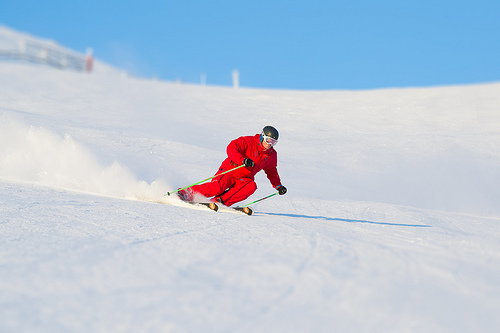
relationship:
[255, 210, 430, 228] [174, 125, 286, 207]
shadow of he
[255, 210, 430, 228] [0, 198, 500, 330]
shadow on snow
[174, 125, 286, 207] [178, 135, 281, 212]
he wearing clothes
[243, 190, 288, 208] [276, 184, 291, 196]
snow pole on left hand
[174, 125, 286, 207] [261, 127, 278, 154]
he wearing goggles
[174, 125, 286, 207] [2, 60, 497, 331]
he on ski slope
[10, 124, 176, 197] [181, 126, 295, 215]
snow behind skier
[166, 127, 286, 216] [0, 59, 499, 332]
he skiing on hill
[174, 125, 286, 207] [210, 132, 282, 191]
he wearing clothes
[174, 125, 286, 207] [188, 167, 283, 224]
he wearing pants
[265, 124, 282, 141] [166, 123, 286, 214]
helmet of him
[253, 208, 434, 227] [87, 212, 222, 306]
shadow cast on snow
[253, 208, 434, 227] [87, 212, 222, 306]
shadow on snow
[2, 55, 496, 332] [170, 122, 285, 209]
snow behind skier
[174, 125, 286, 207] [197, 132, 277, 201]
he wearing jumpsuit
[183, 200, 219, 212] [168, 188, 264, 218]
ski digging through snow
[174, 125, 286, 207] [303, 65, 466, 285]
he skiing down slope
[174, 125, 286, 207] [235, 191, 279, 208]
he holds snow pole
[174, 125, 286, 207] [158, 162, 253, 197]
he holds pole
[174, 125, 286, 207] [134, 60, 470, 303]
he going down hill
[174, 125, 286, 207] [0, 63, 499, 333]
he skiing down ski slope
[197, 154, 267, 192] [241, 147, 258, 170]
pole in hand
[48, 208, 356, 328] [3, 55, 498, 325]
ski marks on hill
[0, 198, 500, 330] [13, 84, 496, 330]
snow above ground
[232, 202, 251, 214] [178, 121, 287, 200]
ski of skier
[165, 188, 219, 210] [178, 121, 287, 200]
ski of skier